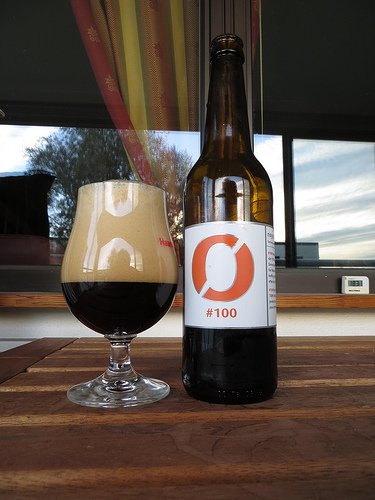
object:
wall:
[0, 309, 372, 340]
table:
[15, 326, 373, 457]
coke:
[60, 179, 179, 335]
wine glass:
[60, 180, 180, 411]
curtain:
[70, 1, 200, 266]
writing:
[159, 237, 173, 248]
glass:
[182, 34, 278, 403]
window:
[1, 124, 288, 266]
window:
[291, 136, 374, 266]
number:
[206, 307, 237, 318]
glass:
[59, 177, 179, 411]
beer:
[61, 281, 176, 333]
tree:
[26, 125, 181, 266]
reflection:
[29, 122, 184, 254]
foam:
[58, 178, 179, 283]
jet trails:
[254, 138, 373, 264]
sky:
[0, 125, 373, 258]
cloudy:
[293, 142, 374, 259]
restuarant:
[0, 69, 375, 493]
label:
[181, 220, 277, 329]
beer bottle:
[179, 33, 277, 407]